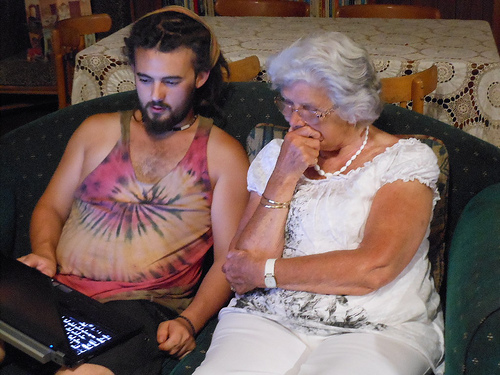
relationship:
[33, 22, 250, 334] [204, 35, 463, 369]
man sitting nex to a woman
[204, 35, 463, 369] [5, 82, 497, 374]
woman on a couch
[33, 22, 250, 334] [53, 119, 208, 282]
man wearing a shirt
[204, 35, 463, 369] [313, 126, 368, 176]
woman wearing a beaded necklace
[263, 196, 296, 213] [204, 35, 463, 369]
bracelets on woman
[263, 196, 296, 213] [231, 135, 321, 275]
bracelets on arm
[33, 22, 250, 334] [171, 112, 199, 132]
man wearing necklace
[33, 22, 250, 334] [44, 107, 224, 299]
man wearing tank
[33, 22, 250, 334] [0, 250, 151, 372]
man using laptop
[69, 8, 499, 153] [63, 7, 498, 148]
tablecloth on table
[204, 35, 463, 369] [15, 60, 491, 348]
woman sitting on couch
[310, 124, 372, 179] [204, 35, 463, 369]
neclace on woman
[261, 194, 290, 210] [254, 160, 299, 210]
bracelets on wrist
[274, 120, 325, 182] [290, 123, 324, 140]
hand to mouth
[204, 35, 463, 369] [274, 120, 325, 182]
woman holding hand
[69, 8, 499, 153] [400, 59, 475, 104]
tablecloth with design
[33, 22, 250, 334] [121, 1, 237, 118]
man with dredd locks